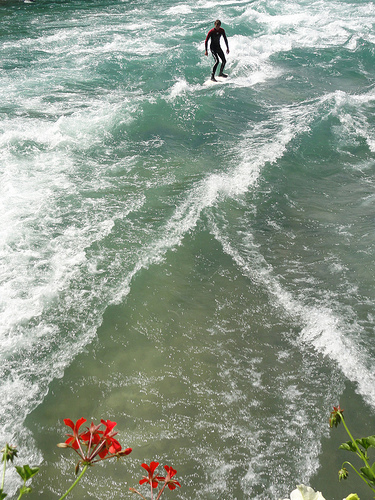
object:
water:
[2, 2, 373, 498]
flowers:
[127, 459, 182, 498]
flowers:
[56, 415, 133, 498]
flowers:
[327, 404, 374, 498]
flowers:
[0, 441, 41, 498]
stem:
[326, 403, 374, 488]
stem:
[154, 479, 169, 500]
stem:
[148, 473, 154, 499]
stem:
[58, 463, 86, 499]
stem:
[16, 481, 26, 500]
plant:
[324, 403, 373, 498]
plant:
[127, 458, 183, 498]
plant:
[47, 413, 132, 498]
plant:
[12, 463, 38, 499]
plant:
[0, 441, 19, 498]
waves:
[0, 1, 374, 498]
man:
[204, 19, 229, 82]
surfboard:
[201, 72, 231, 86]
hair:
[214, 19, 221, 27]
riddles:
[89, 96, 292, 221]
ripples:
[183, 373, 249, 447]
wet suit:
[204, 26, 229, 74]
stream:
[0, 0, 375, 500]